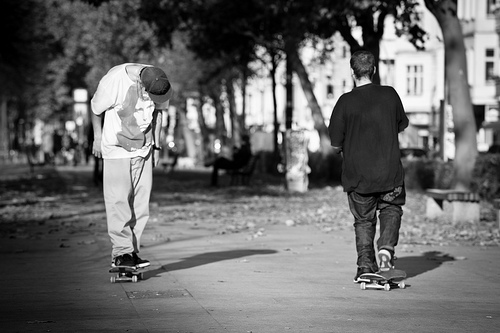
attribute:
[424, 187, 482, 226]
bench — concrete, wood, cement, empty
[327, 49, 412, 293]
skateboarder — skateboarding, pushing off, male, skating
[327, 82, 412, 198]
shirt — black, dark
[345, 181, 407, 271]
jeans — blue, dark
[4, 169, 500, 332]
pavement — concrete, grey, wide, shaded, tree lined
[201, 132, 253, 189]
man — sitting, skateboarding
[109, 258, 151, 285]
skateboard — rolling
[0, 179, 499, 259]
leaves — scattered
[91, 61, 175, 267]
man — skateboarding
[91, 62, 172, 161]
tshirt — white, light color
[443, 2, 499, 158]
building — white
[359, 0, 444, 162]
building — white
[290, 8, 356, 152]
building — white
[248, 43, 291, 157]
tree — white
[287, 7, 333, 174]
tree — shady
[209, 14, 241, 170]
tree — shady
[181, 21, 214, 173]
tree — shady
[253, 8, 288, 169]
tree — shady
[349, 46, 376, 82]
hair — short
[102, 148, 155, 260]
pants — khaki, light color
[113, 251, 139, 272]
shoe — skateboard shoe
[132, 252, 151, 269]
shoe — skateboard shoe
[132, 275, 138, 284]
wheel — white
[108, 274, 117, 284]
wheel — white